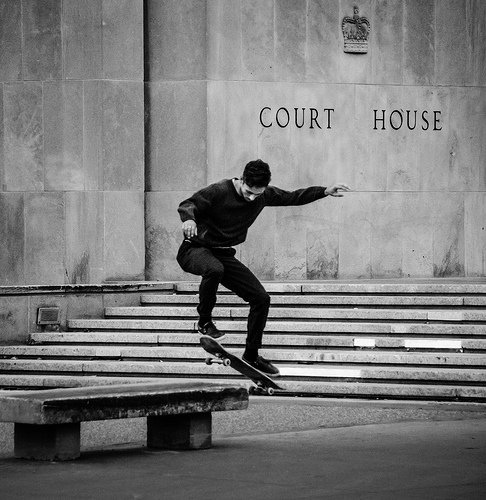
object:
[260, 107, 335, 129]
word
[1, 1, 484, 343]
building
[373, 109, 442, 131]
word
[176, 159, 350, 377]
man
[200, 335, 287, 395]
skateboard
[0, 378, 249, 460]
bench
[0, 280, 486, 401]
steps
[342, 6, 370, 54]
crown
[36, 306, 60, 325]
vent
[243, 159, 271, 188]
hair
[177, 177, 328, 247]
shirt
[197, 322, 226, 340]
sneaker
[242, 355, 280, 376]
sneaker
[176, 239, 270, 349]
pants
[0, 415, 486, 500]
ground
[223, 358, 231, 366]
wheel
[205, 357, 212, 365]
wheel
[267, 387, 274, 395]
wheel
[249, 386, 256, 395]
wheel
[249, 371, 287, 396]
edge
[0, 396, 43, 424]
edge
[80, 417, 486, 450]
seam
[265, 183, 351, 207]
arm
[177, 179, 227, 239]
arm